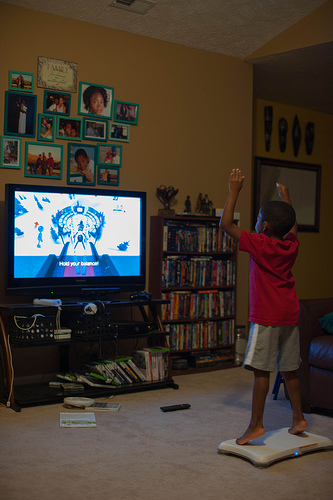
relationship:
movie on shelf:
[164, 228, 231, 344] [150, 215, 239, 376]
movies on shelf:
[161, 255, 234, 287] [150, 215, 239, 376]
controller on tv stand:
[129, 290, 150, 299] [4, 297, 179, 411]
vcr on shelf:
[111, 319, 151, 336] [2, 296, 181, 412]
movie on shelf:
[191, 293, 194, 319] [160, 290, 236, 318]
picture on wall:
[74, 78, 115, 122] [2, 1, 331, 373]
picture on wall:
[110, 98, 143, 129] [2, 1, 331, 373]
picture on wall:
[5, 66, 37, 94] [2, 1, 331, 373]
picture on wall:
[46, 92, 70, 114] [2, 1, 331, 373]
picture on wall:
[59, 138, 100, 189] [2, 1, 331, 373]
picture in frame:
[69, 144, 95, 183] [67, 142, 95, 186]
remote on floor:
[160, 396, 194, 419] [78, 443, 171, 486]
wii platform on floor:
[213, 424, 325, 460] [0, 364, 332, 499]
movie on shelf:
[205, 225, 209, 253] [150, 215, 239, 376]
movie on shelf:
[204, 261, 210, 285] [150, 215, 239, 376]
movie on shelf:
[168, 293, 173, 322] [150, 215, 239, 376]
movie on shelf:
[190, 322, 195, 350] [150, 215, 239, 376]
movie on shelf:
[199, 258, 207, 287] [143, 202, 242, 378]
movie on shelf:
[179, 290, 186, 321] [143, 202, 242, 378]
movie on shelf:
[202, 319, 212, 347] [143, 202, 242, 378]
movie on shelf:
[226, 291, 230, 316] [158, 315, 238, 320]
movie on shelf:
[211, 258, 217, 286] [150, 215, 239, 376]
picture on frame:
[7, 69, 36, 93] [5, 69, 37, 94]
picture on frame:
[39, 89, 73, 115] [43, 91, 69, 113]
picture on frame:
[80, 84, 112, 116] [74, 77, 117, 120]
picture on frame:
[116, 101, 137, 121] [112, 98, 141, 125]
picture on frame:
[8, 94, 33, 134] [2, 89, 39, 138]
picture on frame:
[37, 114, 56, 140] [37, 112, 56, 142]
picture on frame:
[77, 116, 114, 145] [74, 74, 117, 116]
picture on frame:
[56, 114, 85, 143] [54, 114, 90, 144]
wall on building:
[150, 53, 241, 209] [4, 6, 332, 484]